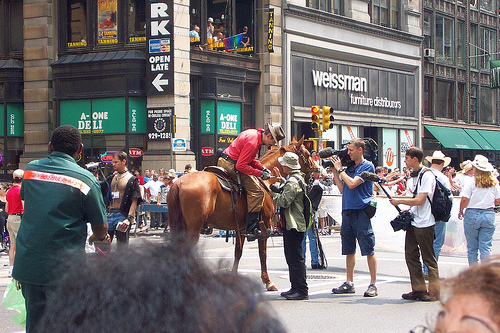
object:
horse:
[167, 134, 334, 292]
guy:
[390, 148, 443, 302]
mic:
[359, 171, 403, 215]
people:
[156, 176, 171, 233]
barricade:
[138, 204, 169, 213]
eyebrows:
[460, 315, 496, 332]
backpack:
[412, 169, 453, 222]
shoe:
[332, 282, 355, 294]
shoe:
[364, 284, 378, 296]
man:
[143, 174, 164, 231]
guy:
[332, 138, 379, 297]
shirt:
[341, 159, 374, 210]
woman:
[457, 155, 500, 266]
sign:
[145, 0, 176, 95]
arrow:
[151, 73, 168, 92]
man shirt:
[223, 128, 264, 177]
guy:
[12, 125, 106, 333]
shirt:
[11, 152, 107, 286]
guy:
[218, 122, 286, 241]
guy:
[270, 152, 312, 301]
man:
[425, 150, 453, 282]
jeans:
[463, 208, 496, 267]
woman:
[409, 253, 496, 333]